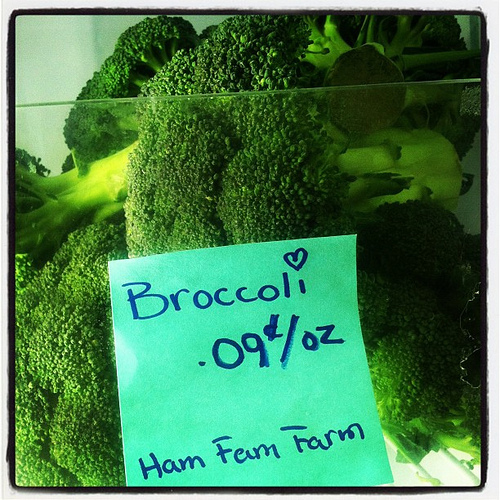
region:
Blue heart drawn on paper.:
[275, 242, 315, 277]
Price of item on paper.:
[190, 299, 343, 387]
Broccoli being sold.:
[119, 127, 241, 213]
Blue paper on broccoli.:
[89, 248, 399, 498]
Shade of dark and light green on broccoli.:
[45, 114, 198, 216]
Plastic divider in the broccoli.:
[42, 82, 189, 222]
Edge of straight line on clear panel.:
[60, 59, 202, 129]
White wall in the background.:
[32, 37, 107, 142]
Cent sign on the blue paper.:
[250, 300, 292, 355]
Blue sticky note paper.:
[95, 220, 392, 455]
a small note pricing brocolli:
[102, 235, 397, 485]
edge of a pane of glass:
[14, 74, 493, 109]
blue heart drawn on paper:
[281, 246, 308, 271]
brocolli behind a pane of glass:
[15, 16, 498, 489]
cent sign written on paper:
[262, 316, 283, 342]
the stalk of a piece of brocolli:
[20, 143, 133, 239]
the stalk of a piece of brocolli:
[327, 135, 462, 214]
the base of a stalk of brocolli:
[327, 44, 404, 131]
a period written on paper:
[197, 359, 207, 369]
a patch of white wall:
[16, 22, 106, 69]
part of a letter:
[171, 434, 206, 473]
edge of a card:
[107, 406, 142, 461]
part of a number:
[236, 346, 263, 399]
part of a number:
[206, 317, 242, 370]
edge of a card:
[359, 368, 401, 413]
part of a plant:
[388, 367, 425, 437]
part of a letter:
[281, 412, 307, 441]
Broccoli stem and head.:
[7, 144, 107, 296]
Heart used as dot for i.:
[275, 245, 336, 295]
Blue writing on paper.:
[128, 272, 275, 385]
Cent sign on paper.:
[256, 300, 288, 359]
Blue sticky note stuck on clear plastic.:
[87, 217, 369, 481]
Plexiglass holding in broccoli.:
[82, 87, 389, 399]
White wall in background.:
[29, 30, 83, 92]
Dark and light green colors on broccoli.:
[55, 136, 193, 265]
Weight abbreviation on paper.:
[292, 307, 359, 387]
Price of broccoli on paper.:
[195, 295, 307, 387]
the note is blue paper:
[88, 229, 395, 491]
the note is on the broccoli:
[100, 222, 395, 488]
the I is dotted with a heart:
[278, 247, 312, 270]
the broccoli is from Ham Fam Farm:
[128, 415, 365, 487]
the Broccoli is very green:
[13, 15, 478, 485]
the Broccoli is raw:
[12, 8, 484, 491]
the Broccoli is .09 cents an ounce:
[188, 301, 353, 387]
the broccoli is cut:
[3, 4, 498, 490]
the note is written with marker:
[95, 229, 395, 499]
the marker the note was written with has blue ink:
[96, 235, 379, 497]